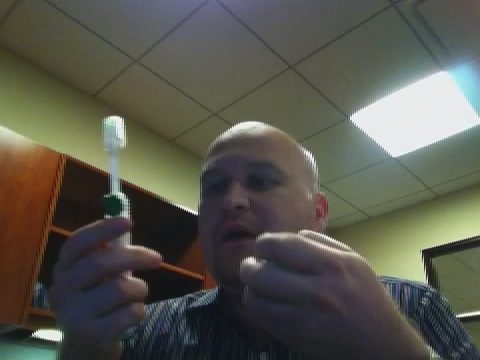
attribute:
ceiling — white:
[138, 11, 386, 94]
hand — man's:
[46, 214, 163, 350]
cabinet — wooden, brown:
[1, 123, 217, 329]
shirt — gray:
[119, 276, 478, 358]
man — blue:
[44, 104, 476, 358]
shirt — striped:
[105, 268, 477, 358]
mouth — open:
[213, 216, 261, 247]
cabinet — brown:
[22, 85, 208, 308]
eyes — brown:
[172, 173, 282, 194]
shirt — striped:
[116, 269, 449, 357]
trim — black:
[206, 0, 298, 75]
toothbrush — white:
[104, 113, 134, 279]